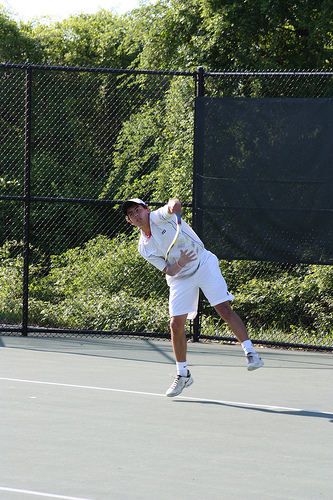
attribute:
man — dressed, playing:
[120, 191, 265, 397]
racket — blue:
[167, 208, 200, 277]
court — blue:
[1, 324, 330, 497]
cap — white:
[123, 197, 151, 210]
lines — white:
[3, 367, 330, 433]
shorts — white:
[159, 255, 226, 313]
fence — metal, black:
[2, 64, 331, 353]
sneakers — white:
[171, 353, 266, 402]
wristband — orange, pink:
[177, 260, 185, 270]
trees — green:
[3, 1, 328, 333]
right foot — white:
[168, 374, 193, 397]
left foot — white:
[246, 349, 265, 372]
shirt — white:
[137, 212, 201, 275]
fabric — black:
[198, 99, 332, 261]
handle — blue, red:
[176, 208, 181, 226]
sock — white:
[174, 360, 192, 376]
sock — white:
[241, 340, 253, 355]